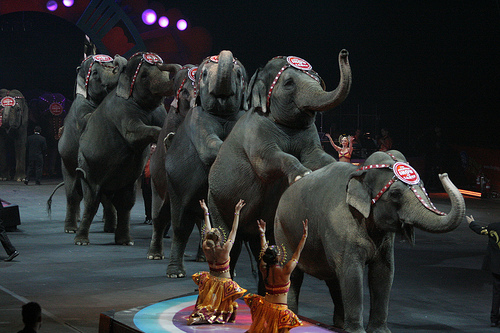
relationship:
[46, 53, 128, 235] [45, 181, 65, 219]
elephant has tail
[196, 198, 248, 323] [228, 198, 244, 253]
woman has arms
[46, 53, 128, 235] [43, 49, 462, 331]
elephant in a line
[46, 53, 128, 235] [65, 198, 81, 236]
elephant has foot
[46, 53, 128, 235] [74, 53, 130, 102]
elephant has head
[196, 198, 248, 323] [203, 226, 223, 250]
woman has hair